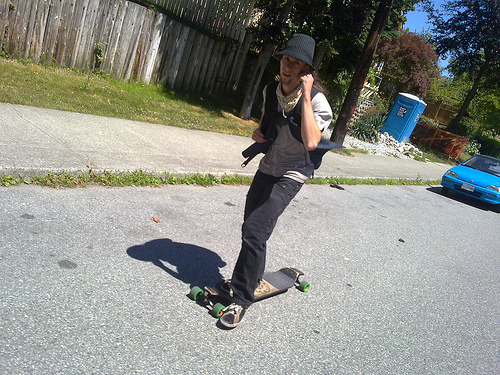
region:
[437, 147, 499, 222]
blue car parked on a street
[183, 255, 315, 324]
skateboard with green wheels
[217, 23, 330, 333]
man on a skateboard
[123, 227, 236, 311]
skater's shadow on the pavement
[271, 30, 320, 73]
skater's black colored hat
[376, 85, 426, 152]
blue and white port a potty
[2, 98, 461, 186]
cement sidewalk near the street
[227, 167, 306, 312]
skater's black colored jeans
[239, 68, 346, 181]
skater's black vest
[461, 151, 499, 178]
windshield on a blue car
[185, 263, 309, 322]
a black skateboard with green wheels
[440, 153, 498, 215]
part of a blue car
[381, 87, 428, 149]
a blue and white porta potty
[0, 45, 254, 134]
a section of green grass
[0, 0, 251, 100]
part of a gray wooden fence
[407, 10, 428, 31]
part of a blue sky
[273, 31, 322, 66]
a black hat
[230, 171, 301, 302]
a man's black jeans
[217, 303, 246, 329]
the shoe of a man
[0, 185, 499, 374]
part of a roadway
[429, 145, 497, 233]
Blue car parked behind skater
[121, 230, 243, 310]
shadow made by the skater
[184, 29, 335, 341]
man riding a skateboard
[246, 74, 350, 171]
man's vest is blowing in the wind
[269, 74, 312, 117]
man is wearing a scarf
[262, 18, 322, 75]
man is wearing a black fadora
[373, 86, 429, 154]
blue port a potty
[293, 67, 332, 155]
man's arm in the air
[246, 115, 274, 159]
hand holding on to the backpack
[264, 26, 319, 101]
man is looking at the camera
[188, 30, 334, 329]
Man on a skateboard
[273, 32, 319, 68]
Black hat on man's head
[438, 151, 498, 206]
Blue car parked on the street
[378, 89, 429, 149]
Port-a-potty along the sidewalk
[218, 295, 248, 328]
Sneaker on boy's foot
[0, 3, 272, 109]
Wooden fence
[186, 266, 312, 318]
Skateboard with green wheels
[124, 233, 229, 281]
Boy's shadow on the ground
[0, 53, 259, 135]
Patch of grass between sidewalk and fence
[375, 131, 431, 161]
White flowers around port-a-potty